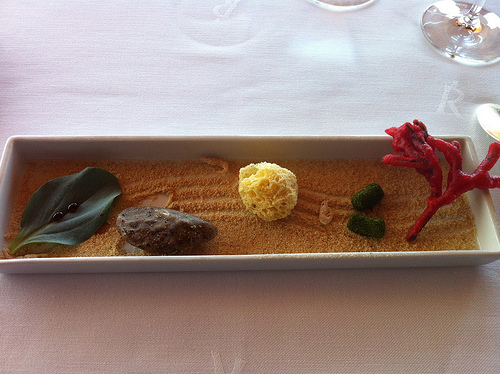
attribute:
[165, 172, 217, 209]
dirt — here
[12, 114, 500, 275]
tray — here, small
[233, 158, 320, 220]
sponge — yellow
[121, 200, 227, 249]
rock — oblong, orange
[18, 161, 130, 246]
leaf — black, here, green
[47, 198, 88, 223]
charcoal — here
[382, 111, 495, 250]
coral — red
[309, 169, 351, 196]
sand — red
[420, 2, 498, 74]
glass — here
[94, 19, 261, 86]
cloth — white, here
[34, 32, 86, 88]
tag — white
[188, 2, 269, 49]
plate — here, rectangual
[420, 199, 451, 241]
stem — red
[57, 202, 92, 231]
beans — black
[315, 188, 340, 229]
stone — small, green